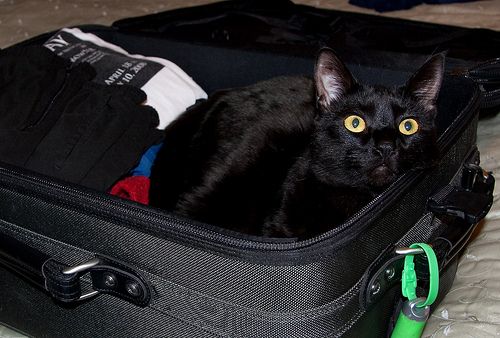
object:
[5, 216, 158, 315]
handle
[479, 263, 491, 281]
part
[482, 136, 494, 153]
part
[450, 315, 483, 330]
part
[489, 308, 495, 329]
part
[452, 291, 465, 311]
part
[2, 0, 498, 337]
mattress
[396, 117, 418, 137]
eye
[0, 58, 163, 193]
gloves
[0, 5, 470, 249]
luggage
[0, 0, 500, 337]
bed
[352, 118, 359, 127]
black pupil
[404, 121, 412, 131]
black pupil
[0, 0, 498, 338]
suit case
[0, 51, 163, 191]
clothes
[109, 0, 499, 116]
lid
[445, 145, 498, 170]
ground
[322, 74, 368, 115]
ground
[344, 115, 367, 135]
cat eyes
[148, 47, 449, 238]
cat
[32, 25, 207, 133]
clothes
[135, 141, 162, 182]
clothing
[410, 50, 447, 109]
ear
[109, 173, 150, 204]
clothing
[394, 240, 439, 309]
tag